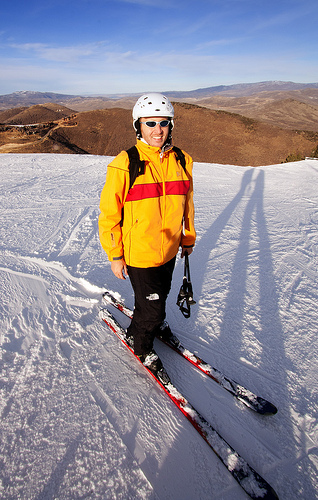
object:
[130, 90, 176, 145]
helmet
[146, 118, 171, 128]
sunglasses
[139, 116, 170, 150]
face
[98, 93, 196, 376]
man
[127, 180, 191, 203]
stripe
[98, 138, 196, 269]
jacket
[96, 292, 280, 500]
skis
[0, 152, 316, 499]
snow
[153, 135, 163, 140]
smile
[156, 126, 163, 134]
nose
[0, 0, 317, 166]
mountains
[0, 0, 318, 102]
sky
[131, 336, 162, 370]
boots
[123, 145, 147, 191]
straps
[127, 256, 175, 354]
pants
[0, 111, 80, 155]
path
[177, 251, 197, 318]
poles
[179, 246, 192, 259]
hand